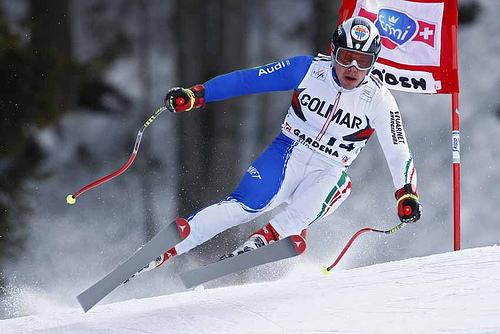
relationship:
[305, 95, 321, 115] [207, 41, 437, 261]
letter on ski suit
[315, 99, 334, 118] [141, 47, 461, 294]
letter on ski suit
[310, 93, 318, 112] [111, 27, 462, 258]
letter on ski suit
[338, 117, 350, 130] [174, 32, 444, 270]
letter on ski suit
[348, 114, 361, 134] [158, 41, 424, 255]
letter on ski suit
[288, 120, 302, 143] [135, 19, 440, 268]
letter on ski suit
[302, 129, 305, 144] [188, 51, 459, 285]
letter on ski suit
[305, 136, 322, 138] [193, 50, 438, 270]
letter on ski suit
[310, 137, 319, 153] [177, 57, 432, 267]
letter on ski suit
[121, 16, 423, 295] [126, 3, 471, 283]
athlete round gate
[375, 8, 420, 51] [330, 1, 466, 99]
logo on flag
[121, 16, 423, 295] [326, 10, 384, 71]
athlete wears helmet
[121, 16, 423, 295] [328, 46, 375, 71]
athlete wears goggles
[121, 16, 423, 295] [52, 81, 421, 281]
athlete holds poles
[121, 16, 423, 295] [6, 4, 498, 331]
athlete in race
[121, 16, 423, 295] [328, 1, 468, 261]
athlete around flag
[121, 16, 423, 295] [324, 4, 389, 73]
athlete has helmet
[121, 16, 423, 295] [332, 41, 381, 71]
athlete has googles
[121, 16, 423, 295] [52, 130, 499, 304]
athlete on turn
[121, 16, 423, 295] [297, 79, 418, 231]
athlete wears white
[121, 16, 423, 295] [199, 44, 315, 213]
athlete wears blue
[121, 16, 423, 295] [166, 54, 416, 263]
athlete wears ski suit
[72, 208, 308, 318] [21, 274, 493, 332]
skis on snow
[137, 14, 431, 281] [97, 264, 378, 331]
athlete on snow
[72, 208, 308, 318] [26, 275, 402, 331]
skis over snow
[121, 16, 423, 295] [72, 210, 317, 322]
athlete on ski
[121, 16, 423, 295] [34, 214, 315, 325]
athlete has skis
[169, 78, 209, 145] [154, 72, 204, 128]
glove on hand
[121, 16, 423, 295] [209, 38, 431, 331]
athlete has outfit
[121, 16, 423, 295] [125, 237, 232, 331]
athlete off ground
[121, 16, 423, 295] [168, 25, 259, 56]
athlete in air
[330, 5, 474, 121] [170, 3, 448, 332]
flag behind skier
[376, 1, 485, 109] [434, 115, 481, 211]
sign on pole